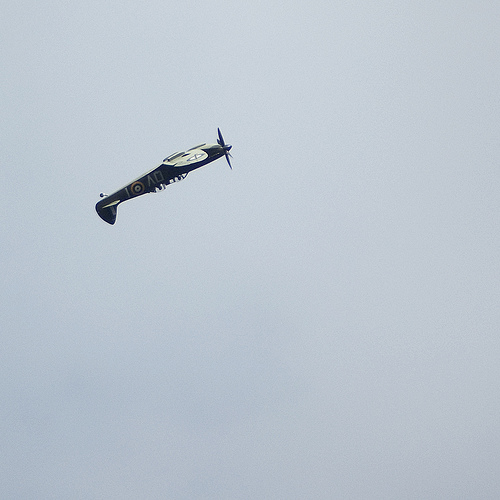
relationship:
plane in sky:
[94, 125, 236, 226] [2, 0, 500, 499]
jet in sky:
[94, 125, 236, 226] [2, 0, 500, 499]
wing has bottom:
[163, 149, 209, 168] [163, 147, 209, 165]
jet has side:
[94, 125, 236, 226] [123, 166, 180, 200]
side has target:
[123, 166, 180, 200] [130, 180, 144, 196]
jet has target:
[94, 125, 236, 226] [130, 180, 144, 196]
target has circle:
[130, 180, 144, 196] [133, 184, 143, 192]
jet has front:
[94, 125, 236, 226] [215, 142, 232, 155]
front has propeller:
[215, 142, 232, 155] [215, 125, 236, 172]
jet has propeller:
[94, 125, 236, 226] [215, 125, 236, 172]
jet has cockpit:
[94, 125, 236, 226] [149, 172, 189, 194]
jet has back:
[94, 125, 236, 226] [94, 191, 121, 227]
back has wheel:
[94, 191, 121, 227] [99, 192, 105, 199]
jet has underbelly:
[94, 125, 236, 226] [128, 141, 220, 189]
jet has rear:
[94, 125, 236, 226] [94, 191, 121, 227]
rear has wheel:
[94, 191, 121, 227] [99, 192, 105, 199]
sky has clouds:
[2, 0, 500, 499] [0, 0, 499, 499]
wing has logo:
[163, 149, 209, 168] [186, 152, 204, 163]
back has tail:
[94, 191, 121, 227] [97, 205, 119, 226]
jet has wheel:
[94, 125, 236, 226] [99, 192, 105, 199]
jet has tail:
[94, 125, 236, 226] [97, 205, 119, 226]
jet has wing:
[94, 125, 236, 226] [163, 149, 209, 168]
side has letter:
[123, 166, 180, 200] [145, 173, 158, 189]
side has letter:
[123, 166, 180, 200] [152, 169, 166, 185]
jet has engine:
[94, 125, 236, 226] [224, 143, 232, 152]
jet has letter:
[94, 125, 236, 226] [145, 173, 158, 189]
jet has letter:
[94, 125, 236, 226] [152, 169, 166, 185]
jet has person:
[94, 125, 236, 226] [156, 183, 165, 191]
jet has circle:
[94, 125, 236, 226] [133, 184, 143, 192]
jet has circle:
[94, 125, 236, 226] [130, 180, 146, 195]